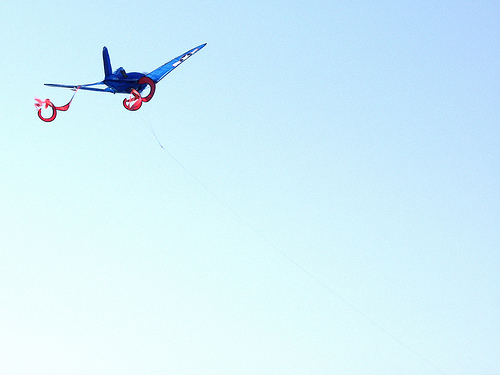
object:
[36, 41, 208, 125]
plane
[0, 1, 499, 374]
sky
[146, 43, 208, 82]
wing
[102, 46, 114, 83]
tail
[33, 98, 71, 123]
flag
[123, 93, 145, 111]
flag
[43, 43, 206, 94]
kite